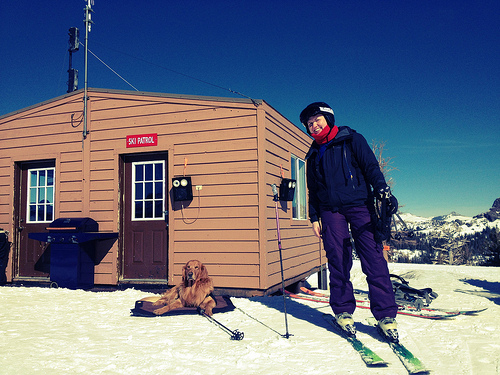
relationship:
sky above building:
[0, 1, 499, 218] [5, 83, 326, 301]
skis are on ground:
[323, 306, 432, 373] [1, 257, 498, 372]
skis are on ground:
[288, 280, 489, 321] [1, 257, 498, 372]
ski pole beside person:
[272, 190, 294, 341] [300, 99, 404, 347]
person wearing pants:
[300, 99, 404, 347] [315, 206, 398, 320]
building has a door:
[5, 83, 326, 301] [118, 158, 167, 282]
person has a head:
[300, 99, 404, 347] [298, 96, 334, 142]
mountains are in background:
[382, 194, 497, 269] [0, 5, 499, 218]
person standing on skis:
[300, 99, 404, 347] [323, 306, 432, 373]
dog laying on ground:
[141, 258, 215, 317] [1, 257, 498, 372]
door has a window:
[118, 158, 167, 282] [130, 159, 167, 224]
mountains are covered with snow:
[382, 194, 497, 269] [386, 212, 497, 263]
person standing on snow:
[300, 99, 404, 347] [1, 257, 498, 372]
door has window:
[118, 158, 167, 282] [130, 159, 167, 224]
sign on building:
[125, 132, 160, 149] [5, 83, 326, 301]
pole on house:
[80, 0, 95, 135] [5, 83, 326, 301]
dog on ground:
[141, 258, 215, 317] [1, 257, 498, 372]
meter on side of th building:
[170, 175, 202, 226] [5, 83, 326, 301]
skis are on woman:
[323, 306, 432, 373] [300, 99, 404, 347]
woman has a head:
[300, 99, 404, 347] [298, 96, 334, 142]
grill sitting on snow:
[28, 219, 119, 293] [0, 286, 280, 373]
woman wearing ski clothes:
[300, 99, 404, 347] [303, 122, 400, 344]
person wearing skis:
[300, 99, 404, 347] [323, 306, 432, 373]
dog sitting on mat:
[141, 258, 215, 317] [128, 289, 231, 318]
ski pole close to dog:
[195, 308, 244, 340] [141, 258, 215, 317]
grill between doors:
[28, 219, 119, 293] [13, 148, 171, 286]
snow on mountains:
[386, 212, 497, 263] [382, 194, 497, 269]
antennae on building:
[82, 1, 91, 141] [5, 83, 326, 301]